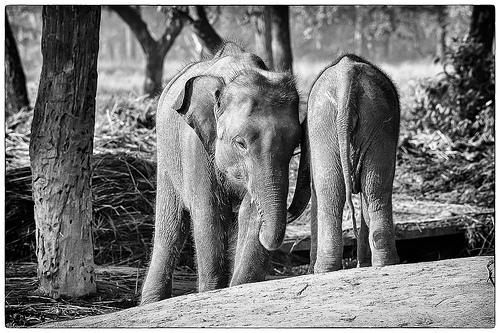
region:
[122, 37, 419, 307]
two baby elephants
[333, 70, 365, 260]
long and thin tail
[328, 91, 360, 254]
tail hanging down the backside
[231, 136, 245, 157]
eye on the side of the head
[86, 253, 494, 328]
small hill on the ground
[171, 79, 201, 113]
tip of the ear is curled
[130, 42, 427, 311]
two elephants standing next to each other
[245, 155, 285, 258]
bottom of the trunk is curled under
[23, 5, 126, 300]
bark on the tree trunk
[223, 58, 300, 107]
hair sticking out of the top of the head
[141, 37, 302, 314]
large grey elephant standing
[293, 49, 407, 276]
large grey elephant standing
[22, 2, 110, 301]
grey and white tree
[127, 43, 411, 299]
a pair of elephants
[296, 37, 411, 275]
elephant facing away from camera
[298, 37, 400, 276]
elephant showing his but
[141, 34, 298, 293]
elephant facing the camera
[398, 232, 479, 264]
dark cave next to elephants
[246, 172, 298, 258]
elephant trunk folded up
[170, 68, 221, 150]
folded elephant ear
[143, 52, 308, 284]
a small hairy elephant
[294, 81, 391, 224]
elephant's behind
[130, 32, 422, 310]
two baby elephants on dirt ground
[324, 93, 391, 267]
elephant tail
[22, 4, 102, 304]
tree trunk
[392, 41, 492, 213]
foliage under tree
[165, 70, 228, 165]
baby elephant ear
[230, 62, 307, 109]
fuzzy baby hair on baby elephant head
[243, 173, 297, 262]
baby elephant trunk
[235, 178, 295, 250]
curled elephant trunk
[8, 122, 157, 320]
straw pile on ground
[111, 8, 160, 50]
tree branch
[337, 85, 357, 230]
visible tail of elephant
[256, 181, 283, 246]
trunk of elephant facing front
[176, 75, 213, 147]
waving ear of elephant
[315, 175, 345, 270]
back leg of elephant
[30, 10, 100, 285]
wooden trunk of the tree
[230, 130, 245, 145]
eye of the elephant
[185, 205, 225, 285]
front leg of elephant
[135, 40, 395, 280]
two elephant captured in pic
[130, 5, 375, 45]
trees visible at background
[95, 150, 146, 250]
dry grass lying on ground